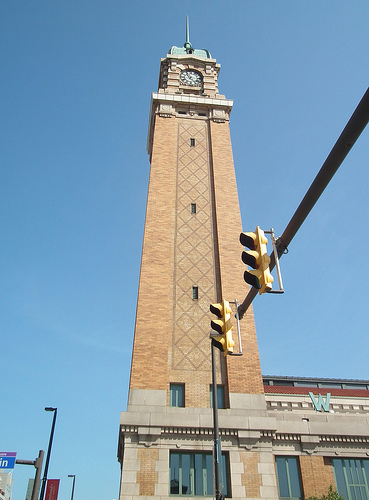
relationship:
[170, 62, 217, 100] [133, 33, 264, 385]
clock on tower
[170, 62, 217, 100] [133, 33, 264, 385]
clock in tower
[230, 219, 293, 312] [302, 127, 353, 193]
light on pole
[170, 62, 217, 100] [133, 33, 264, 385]
clock near tower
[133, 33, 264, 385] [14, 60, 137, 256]
tower in sky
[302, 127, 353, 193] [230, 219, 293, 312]
pole near light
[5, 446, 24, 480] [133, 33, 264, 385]
sign below tower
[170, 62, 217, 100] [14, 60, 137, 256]
clock in sky